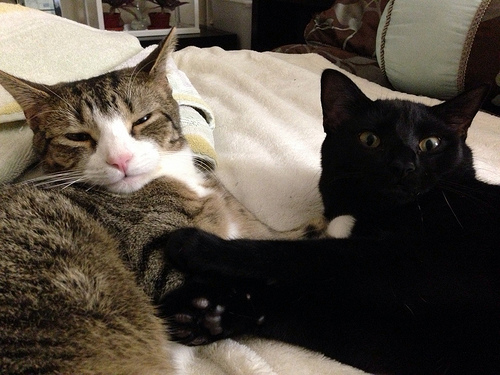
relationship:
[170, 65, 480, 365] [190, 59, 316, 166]
black cat lying on a blanket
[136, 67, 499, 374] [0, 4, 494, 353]
black cat laying on a bed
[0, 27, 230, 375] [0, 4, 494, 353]
cat laying on a bed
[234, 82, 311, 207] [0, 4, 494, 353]
duvet on bed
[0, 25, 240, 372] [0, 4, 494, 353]
cat on bed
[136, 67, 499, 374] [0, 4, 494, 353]
black cat on bed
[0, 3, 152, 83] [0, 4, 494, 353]
pillow on bed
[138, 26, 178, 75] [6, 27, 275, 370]
right ear of a cat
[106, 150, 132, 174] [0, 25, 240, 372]
nose of a cat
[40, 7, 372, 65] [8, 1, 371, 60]
bookshelf in background